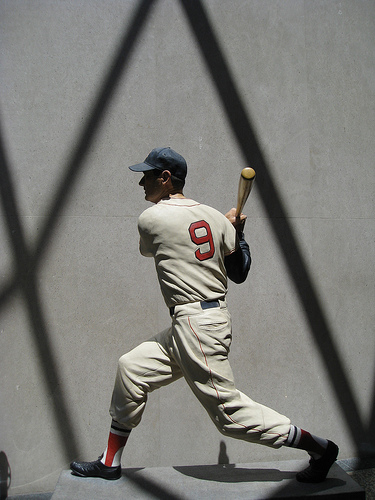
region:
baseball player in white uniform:
[70, 146, 338, 487]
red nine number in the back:
[189, 220, 216, 262]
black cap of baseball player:
[130, 144, 187, 183]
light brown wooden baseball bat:
[234, 166, 253, 227]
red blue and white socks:
[91, 417, 307, 472]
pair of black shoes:
[65, 440, 339, 477]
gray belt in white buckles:
[170, 298, 228, 313]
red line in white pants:
[185, 318, 283, 437]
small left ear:
[158, 167, 170, 184]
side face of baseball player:
[136, 151, 189, 209]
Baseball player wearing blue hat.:
[125, 149, 202, 210]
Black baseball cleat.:
[66, 457, 122, 482]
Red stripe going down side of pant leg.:
[183, 310, 292, 447]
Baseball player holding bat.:
[130, 142, 264, 313]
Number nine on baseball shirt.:
[148, 199, 239, 308]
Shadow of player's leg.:
[173, 457, 295, 489]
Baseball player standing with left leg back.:
[129, 160, 343, 494]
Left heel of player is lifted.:
[293, 434, 344, 492]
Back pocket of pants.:
[193, 305, 232, 344]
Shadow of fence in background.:
[0, 57, 104, 445]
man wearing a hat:
[129, 128, 207, 188]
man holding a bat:
[221, 165, 268, 228]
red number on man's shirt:
[176, 211, 214, 264]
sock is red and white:
[86, 405, 143, 470]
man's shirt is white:
[119, 191, 245, 318]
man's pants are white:
[111, 300, 312, 480]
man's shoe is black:
[58, 446, 128, 487]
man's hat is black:
[115, 138, 183, 179]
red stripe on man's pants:
[178, 304, 268, 448]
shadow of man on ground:
[168, 442, 276, 496]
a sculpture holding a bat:
[101, 112, 304, 498]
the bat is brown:
[216, 150, 258, 261]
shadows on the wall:
[0, 173, 89, 417]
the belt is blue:
[157, 290, 232, 330]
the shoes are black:
[57, 430, 322, 498]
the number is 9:
[185, 212, 218, 279]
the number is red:
[185, 212, 227, 274]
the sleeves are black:
[224, 237, 257, 285]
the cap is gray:
[126, 150, 224, 195]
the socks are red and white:
[72, 406, 327, 492]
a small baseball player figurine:
[65, 135, 346, 492]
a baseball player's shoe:
[61, 454, 128, 484]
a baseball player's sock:
[96, 410, 133, 466]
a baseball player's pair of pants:
[96, 296, 292, 450]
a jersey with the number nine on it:
[130, 198, 260, 307]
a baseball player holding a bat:
[121, 128, 267, 311]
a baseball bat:
[232, 162, 260, 227]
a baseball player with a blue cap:
[123, 135, 198, 212]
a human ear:
[159, 166, 171, 186]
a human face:
[134, 166, 161, 205]